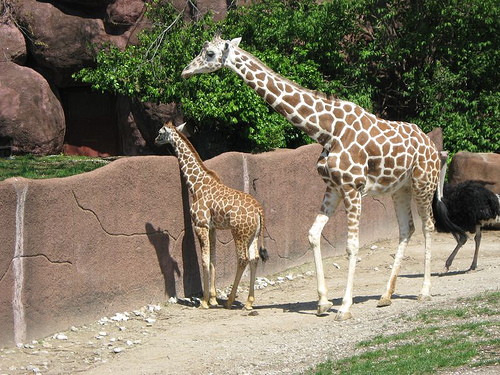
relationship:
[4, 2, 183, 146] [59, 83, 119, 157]
rocks form opening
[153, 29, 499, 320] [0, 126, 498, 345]
animals in cement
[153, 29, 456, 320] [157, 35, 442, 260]
animals have spots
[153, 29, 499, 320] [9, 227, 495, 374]
animals are on gravel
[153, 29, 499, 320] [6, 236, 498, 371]
animals on dirt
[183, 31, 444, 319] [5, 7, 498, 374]
giraffe on a zoo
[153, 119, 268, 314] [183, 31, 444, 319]
baby near mom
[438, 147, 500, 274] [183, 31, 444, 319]
rhea behind giraffe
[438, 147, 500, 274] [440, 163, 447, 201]
rhea has neck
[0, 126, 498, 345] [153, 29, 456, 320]
cement of giraffe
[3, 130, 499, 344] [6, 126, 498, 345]
fence made of cement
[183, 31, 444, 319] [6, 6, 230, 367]
giraffe facing left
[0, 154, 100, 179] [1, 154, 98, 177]
patch of grass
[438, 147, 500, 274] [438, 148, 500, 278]
ostrich standing upright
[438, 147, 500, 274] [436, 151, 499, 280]
ostrich an adult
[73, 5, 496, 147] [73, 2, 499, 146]
leafy green tree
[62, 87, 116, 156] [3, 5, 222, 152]
red rock wall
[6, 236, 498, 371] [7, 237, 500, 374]
dirt portion of path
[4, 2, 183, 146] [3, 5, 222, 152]
rock portion of wall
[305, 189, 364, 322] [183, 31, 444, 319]
legs of giraffe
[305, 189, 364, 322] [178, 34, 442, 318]
legs of adult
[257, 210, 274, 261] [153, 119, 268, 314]
tail of baby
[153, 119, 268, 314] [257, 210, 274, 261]
baby giraffe tail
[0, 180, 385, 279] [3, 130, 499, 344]
crack on wall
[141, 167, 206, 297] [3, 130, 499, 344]
shadow on wall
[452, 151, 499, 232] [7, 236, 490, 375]
stone on ground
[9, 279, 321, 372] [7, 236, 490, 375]
white on ground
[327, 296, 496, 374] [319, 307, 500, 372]
blade of grass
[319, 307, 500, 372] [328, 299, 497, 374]
grass green cluster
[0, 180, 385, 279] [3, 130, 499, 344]
crack in wall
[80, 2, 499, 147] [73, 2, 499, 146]
cluster green trees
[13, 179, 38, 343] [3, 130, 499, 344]
line in wall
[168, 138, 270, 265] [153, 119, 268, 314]
brown and white baby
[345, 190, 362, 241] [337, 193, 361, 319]
spot on leg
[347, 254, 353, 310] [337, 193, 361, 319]
white on leg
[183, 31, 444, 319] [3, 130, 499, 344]
giraffe over wall